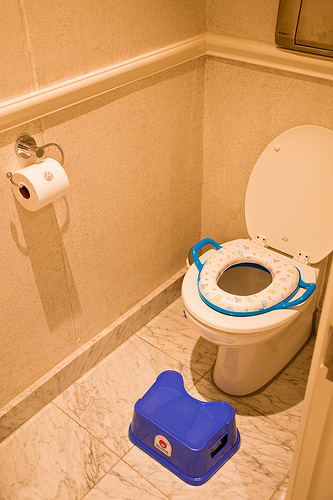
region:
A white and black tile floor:
[55, 364, 289, 495]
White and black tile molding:
[19, 249, 170, 393]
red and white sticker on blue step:
[155, 436, 171, 453]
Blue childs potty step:
[129, 368, 240, 484]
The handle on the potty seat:
[185, 238, 223, 266]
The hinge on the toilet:
[250, 233, 266, 246]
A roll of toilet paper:
[12, 157, 71, 210]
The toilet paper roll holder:
[3, 137, 77, 212]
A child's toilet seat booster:
[183, 239, 316, 317]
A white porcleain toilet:
[179, 126, 331, 396]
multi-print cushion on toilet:
[173, 204, 319, 363]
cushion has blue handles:
[167, 224, 321, 326]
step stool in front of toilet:
[114, 351, 250, 488]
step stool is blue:
[110, 357, 251, 490]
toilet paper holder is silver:
[0, 129, 81, 221]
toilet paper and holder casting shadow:
[9, 118, 98, 342]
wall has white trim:
[4, 13, 332, 144]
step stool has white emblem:
[115, 372, 251, 477]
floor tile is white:
[10, 405, 130, 498]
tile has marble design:
[20, 409, 124, 494]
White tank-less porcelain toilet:
[183, 124, 313, 395]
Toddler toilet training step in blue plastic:
[122, 369, 260, 486]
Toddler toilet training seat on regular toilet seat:
[186, 231, 315, 316]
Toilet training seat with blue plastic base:
[184, 235, 314, 325]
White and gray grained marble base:
[15, 328, 131, 423]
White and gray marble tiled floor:
[9, 409, 126, 496]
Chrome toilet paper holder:
[5, 133, 68, 209]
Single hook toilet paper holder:
[4, 133, 71, 210]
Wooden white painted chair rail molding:
[141, 28, 269, 80]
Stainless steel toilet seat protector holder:
[272, 0, 331, 58]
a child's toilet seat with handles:
[188, 232, 316, 314]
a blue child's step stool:
[129, 365, 242, 482]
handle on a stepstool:
[201, 430, 230, 459]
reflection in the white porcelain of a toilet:
[220, 350, 262, 382]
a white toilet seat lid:
[239, 119, 331, 252]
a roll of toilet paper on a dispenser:
[8, 133, 77, 210]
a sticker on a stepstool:
[152, 429, 175, 459]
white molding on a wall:
[48, 34, 207, 111]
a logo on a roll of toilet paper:
[39, 170, 57, 182]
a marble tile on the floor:
[92, 377, 122, 426]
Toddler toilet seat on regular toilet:
[188, 233, 317, 321]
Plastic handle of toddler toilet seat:
[184, 237, 226, 271]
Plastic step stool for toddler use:
[123, 368, 246, 487]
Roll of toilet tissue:
[7, 156, 71, 212]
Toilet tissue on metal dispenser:
[4, 134, 72, 218]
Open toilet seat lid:
[239, 123, 329, 265]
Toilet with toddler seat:
[177, 123, 332, 401]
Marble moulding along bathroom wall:
[0, 258, 186, 447]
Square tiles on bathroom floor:
[0, 285, 318, 498]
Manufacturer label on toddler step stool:
[150, 432, 172, 459]